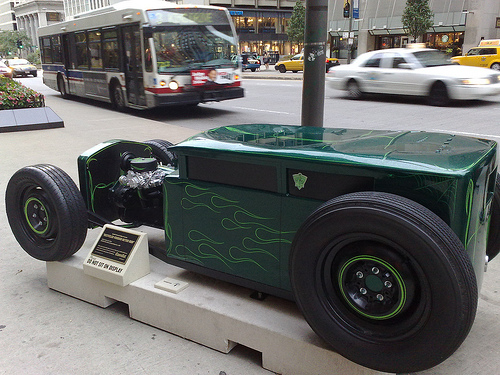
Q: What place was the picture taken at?
A: It was taken at the city.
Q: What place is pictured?
A: It is a city.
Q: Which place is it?
A: It is a city.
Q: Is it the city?
A: Yes, it is the city.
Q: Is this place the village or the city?
A: It is the city.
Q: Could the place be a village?
A: No, it is a city.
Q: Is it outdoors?
A: Yes, it is outdoors.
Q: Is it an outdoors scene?
A: Yes, it is outdoors.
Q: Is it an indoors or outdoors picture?
A: It is outdoors.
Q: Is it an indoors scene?
A: No, it is outdoors.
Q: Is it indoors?
A: No, it is outdoors.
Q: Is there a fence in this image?
A: No, there are no fences.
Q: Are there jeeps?
A: No, there are no jeeps.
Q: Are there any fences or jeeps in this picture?
A: No, there are no jeeps or fences.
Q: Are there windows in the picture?
A: Yes, there is a window.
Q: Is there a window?
A: Yes, there is a window.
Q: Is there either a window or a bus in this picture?
A: Yes, there is a window.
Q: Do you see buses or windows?
A: Yes, there is a window.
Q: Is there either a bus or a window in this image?
A: Yes, there is a window.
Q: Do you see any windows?
A: Yes, there is a window.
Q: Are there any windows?
A: Yes, there is a window.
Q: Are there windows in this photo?
A: Yes, there is a window.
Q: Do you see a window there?
A: Yes, there is a window.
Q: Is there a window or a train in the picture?
A: Yes, there is a window.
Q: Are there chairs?
A: No, there are no chairs.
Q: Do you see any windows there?
A: Yes, there is a window.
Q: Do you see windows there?
A: Yes, there is a window.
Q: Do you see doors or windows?
A: Yes, there is a window.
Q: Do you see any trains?
A: No, there are no trains.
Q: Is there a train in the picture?
A: No, there are no trains.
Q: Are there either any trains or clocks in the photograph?
A: No, there are no trains or clocks.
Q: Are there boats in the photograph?
A: No, there are no boats.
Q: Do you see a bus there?
A: Yes, there is a bus.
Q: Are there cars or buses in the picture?
A: Yes, there is a bus.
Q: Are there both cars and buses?
A: Yes, there are both a bus and a car.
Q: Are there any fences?
A: No, there are no fences.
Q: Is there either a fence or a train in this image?
A: No, there are no fences or trains.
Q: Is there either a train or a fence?
A: No, there are no fences or trains.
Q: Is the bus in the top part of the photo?
A: Yes, the bus is in the top of the image.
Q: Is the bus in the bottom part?
A: No, the bus is in the top of the image.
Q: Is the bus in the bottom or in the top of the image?
A: The bus is in the top of the image.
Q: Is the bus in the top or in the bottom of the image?
A: The bus is in the top of the image.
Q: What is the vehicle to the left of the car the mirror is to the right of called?
A: The vehicle is a bus.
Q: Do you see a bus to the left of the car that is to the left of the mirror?
A: Yes, there is a bus to the left of the car.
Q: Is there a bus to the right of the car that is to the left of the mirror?
A: No, the bus is to the left of the car.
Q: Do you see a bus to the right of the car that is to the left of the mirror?
A: No, the bus is to the left of the car.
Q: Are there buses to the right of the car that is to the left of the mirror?
A: No, the bus is to the left of the car.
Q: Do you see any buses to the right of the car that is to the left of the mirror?
A: No, the bus is to the left of the car.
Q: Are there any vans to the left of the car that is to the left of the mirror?
A: No, there is a bus to the left of the car.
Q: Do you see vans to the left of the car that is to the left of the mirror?
A: No, there is a bus to the left of the car.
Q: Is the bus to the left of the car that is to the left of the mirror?
A: Yes, the bus is to the left of the car.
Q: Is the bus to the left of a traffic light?
A: No, the bus is to the left of the car.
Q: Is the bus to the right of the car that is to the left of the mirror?
A: No, the bus is to the left of the car.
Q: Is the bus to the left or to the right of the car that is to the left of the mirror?
A: The bus is to the left of the car.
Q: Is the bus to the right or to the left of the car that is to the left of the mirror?
A: The bus is to the left of the car.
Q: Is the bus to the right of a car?
A: No, the bus is to the left of a car.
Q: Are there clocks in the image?
A: No, there are no clocks.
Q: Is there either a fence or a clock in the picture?
A: No, there are no clocks or fences.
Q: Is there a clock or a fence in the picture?
A: No, there are no clocks or fences.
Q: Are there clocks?
A: No, there are no clocks.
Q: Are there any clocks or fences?
A: No, there are no clocks or fences.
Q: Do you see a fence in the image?
A: No, there are no fences.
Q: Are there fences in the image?
A: No, there are no fences.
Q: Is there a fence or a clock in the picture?
A: No, there are no fences or clocks.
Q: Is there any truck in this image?
A: No, there are no trucks.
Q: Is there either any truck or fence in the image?
A: No, there are no trucks or fences.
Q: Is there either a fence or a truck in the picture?
A: No, there are no trucks or fences.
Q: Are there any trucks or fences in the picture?
A: No, there are no trucks or fences.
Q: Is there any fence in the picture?
A: No, there are no fences.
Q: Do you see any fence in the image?
A: No, there are no fences.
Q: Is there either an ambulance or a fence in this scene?
A: No, there are no fences or ambulances.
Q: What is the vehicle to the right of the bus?
A: The vehicle is a car.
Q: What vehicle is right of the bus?
A: The vehicle is a car.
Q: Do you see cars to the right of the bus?
A: Yes, there is a car to the right of the bus.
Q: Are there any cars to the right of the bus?
A: Yes, there is a car to the right of the bus.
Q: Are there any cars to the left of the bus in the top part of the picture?
A: No, the car is to the right of the bus.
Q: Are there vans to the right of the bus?
A: No, there is a car to the right of the bus.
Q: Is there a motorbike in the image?
A: No, there are no motorcycles.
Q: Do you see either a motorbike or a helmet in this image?
A: No, there are no motorcycles or helmets.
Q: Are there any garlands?
A: No, there are no garlands.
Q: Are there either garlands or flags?
A: No, there are no garlands or flags.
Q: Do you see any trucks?
A: No, there are no trucks.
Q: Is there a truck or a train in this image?
A: No, there are no trucks or trains.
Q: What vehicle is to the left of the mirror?
A: The vehicle is a car.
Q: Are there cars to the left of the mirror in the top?
A: Yes, there is a car to the left of the mirror.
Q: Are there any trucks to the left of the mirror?
A: No, there is a car to the left of the mirror.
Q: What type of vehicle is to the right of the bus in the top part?
A: The vehicle is a car.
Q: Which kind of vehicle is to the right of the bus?
A: The vehicle is a car.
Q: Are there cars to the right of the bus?
A: Yes, there is a car to the right of the bus.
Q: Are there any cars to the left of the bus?
A: No, the car is to the right of the bus.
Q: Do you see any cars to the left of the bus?
A: No, the car is to the right of the bus.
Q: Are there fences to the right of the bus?
A: No, there is a car to the right of the bus.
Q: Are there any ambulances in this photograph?
A: No, there are no ambulances.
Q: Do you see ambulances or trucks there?
A: No, there are no ambulances or trucks.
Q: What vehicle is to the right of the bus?
A: The vehicle is a car.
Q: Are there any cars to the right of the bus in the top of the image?
A: Yes, there is a car to the right of the bus.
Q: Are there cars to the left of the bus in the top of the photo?
A: No, the car is to the right of the bus.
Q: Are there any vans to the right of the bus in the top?
A: No, there is a car to the right of the bus.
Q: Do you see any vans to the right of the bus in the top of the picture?
A: No, there is a car to the right of the bus.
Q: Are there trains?
A: No, there are no trains.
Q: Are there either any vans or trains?
A: No, there are no trains or vans.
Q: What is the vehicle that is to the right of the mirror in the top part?
A: The vehicle is a car.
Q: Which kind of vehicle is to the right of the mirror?
A: The vehicle is a car.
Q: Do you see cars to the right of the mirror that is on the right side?
A: Yes, there is a car to the right of the mirror.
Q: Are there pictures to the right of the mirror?
A: No, there is a car to the right of the mirror.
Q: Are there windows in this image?
A: Yes, there are windows.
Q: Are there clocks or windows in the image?
A: Yes, there are windows.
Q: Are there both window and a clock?
A: No, there are windows but no clocks.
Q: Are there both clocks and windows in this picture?
A: No, there are windows but no clocks.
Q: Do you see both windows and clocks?
A: No, there are windows but no clocks.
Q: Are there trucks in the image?
A: No, there are no trucks.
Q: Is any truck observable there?
A: No, there are no trucks.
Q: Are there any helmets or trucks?
A: No, there are no trucks or helmets.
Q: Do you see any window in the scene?
A: Yes, there are windows.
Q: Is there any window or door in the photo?
A: Yes, there are windows.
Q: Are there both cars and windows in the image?
A: Yes, there are both windows and a car.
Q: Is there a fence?
A: No, there are no fences.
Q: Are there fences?
A: No, there are no fences.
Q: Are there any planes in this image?
A: No, there are no planes.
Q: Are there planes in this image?
A: No, there are no planes.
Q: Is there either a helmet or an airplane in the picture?
A: No, there are no airplanes or helmets.